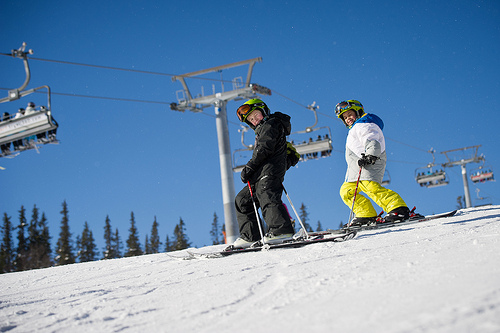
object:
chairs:
[0, 85, 62, 158]